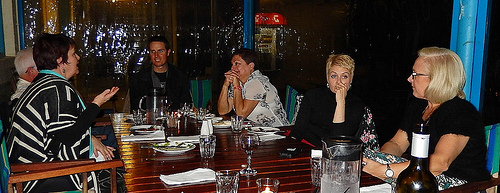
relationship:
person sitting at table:
[365, 44, 481, 177] [110, 102, 389, 191]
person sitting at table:
[296, 52, 366, 152] [110, 102, 389, 191]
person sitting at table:
[9, 34, 119, 191] [110, 102, 389, 191]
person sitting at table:
[361, 45, 481, 177] [110, 102, 389, 191]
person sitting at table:
[292, 50, 364, 152] [110, 102, 389, 191]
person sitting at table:
[217, 47, 289, 124] [110, 102, 389, 191]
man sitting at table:
[128, 36, 188, 116] [110, 102, 389, 191]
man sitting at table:
[128, 36, 188, 116] [102, 89, 469, 191]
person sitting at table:
[9, 34, 119, 191] [69, 79, 299, 171]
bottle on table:
[397, 121, 437, 191] [76, 93, 498, 190]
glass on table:
[198, 134, 216, 161] [108, 111, 394, 191]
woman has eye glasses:
[368, 43, 488, 188] [406, 67, 431, 80]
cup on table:
[255, 177, 278, 192] [108, 111, 394, 191]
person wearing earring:
[296, 52, 366, 152] [54, 51, 61, 70]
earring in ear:
[54, 51, 61, 70] [324, 73, 329, 87]